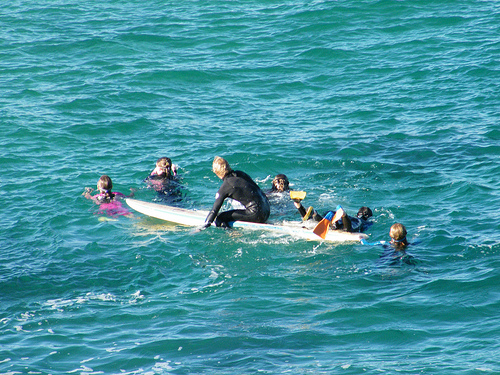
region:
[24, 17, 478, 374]
the water is blue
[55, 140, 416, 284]
children are swimming around a surfboard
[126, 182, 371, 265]
the surfboard is yellow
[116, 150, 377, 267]
a man is sitting on the surfboard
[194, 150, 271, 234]
the man is wearing a black wet suit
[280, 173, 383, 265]
some of the children are wearing flippers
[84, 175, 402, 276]
the surfboard is long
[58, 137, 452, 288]
children are in the water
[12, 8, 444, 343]
the water is calm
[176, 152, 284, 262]
the man's arm is in the water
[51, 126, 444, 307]
several people swimming in the ocean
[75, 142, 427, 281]
one person on a surf board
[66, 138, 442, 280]
surfer with several swimmers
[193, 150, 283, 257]
person in a wet suit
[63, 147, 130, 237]
person treading water in the ocean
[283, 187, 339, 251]
person wearing flippers on their feet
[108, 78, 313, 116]
ripples and waves on the ocean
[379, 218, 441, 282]
girl with ponytail treading water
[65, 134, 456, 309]
girls learning how to swim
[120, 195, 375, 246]
long white surf board in the ocean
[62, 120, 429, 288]
lady on surf board amid swimmers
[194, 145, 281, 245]
person on a wet suit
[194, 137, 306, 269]
person teaching a surf class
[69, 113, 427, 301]
group of people swimming in the ocean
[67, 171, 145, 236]
swimming girl in pink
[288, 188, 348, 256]
orange set of flippers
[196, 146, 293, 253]
blonde lady with a bun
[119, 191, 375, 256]
white surf board in the ocean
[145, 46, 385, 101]
ripples and waves in the ocean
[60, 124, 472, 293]
people learning how to surf in the ocean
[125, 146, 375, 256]
man on a surfboard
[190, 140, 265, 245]
man in a black surf suit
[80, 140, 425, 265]
people swimming in the ocean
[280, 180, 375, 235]
swimmers with flippers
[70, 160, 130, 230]
female in a pink suit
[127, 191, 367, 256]
white surfboard with blue stripe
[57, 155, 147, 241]
woman swimming in front of a surfboard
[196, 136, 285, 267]
blonde man on a surfboard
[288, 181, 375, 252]
people snorkeling in the ocean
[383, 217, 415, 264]
Person with blonde hair in water.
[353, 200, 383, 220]
Person has dark hair.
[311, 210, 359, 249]
Orange and blue flipper.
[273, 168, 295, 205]
Person has dark hair.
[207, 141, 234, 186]
Person has light color hair.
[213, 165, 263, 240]
Person wearing wet suit.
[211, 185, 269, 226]
Person's wet suit is black.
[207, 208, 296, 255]
Person sitting on surfboard.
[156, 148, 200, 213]
Person has dark hair.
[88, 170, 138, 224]
Person has dark hair.